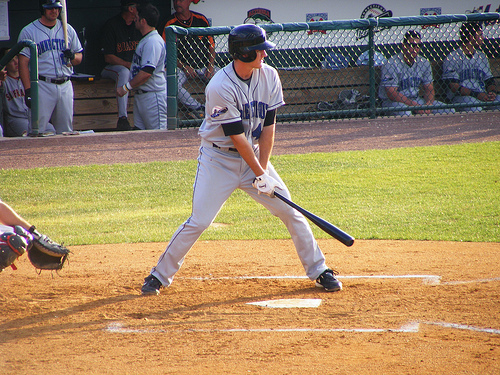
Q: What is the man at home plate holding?
A: A bat.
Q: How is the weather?
A: Sunny.